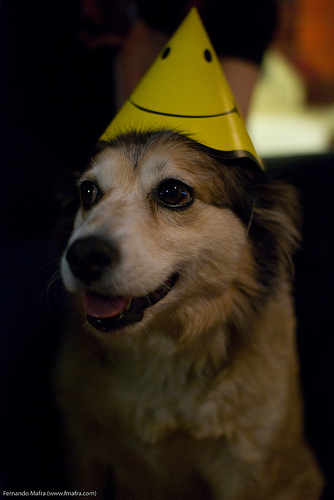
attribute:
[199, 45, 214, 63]
spot — black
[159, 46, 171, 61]
spot — black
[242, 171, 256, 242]
band — thin, white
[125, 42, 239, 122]
face — yellow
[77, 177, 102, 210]
eye — big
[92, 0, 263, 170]
hat — yellow, cone shaped, worn, pointed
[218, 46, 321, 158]
object — white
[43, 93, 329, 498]
dog — here, brown, happy, puppy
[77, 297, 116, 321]
tongue — pink, here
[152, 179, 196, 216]
eye — clear, black, whitish, big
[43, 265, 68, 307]
whiskers — small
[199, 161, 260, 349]
fur — brown, black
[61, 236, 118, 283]
nose — black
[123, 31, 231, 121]
face — smiley